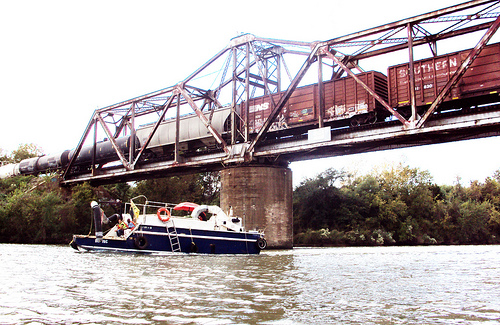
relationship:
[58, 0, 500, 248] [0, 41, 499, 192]
bridge has a train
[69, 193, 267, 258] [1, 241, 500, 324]
boat in water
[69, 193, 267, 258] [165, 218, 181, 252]
boat has a ladder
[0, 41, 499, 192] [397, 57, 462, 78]
train has writing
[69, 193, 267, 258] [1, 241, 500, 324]
boat on water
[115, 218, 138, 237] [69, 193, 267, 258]
people are on boat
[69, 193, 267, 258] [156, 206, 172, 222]
boat has a life saver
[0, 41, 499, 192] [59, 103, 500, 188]
train on tracks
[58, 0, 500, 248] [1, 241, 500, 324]
bridge above water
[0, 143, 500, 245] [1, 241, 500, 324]
trees are near water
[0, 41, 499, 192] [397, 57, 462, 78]
train has large lettering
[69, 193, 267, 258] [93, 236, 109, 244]
boat has writing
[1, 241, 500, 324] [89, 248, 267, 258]
water has shadows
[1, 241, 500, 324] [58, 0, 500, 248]
water under a bridge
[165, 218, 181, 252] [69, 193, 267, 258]
ladder on a boat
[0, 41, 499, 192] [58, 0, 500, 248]
train on a bridge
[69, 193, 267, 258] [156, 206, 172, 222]
boat has a life preserver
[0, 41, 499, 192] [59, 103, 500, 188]
train running on tracks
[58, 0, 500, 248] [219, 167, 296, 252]
bridge has a cement pier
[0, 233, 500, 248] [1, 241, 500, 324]
rocks are alongside water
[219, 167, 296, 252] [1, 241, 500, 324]
concrete pillar in water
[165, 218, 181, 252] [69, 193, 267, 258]
ladder on side of a boat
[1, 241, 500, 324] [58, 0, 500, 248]
water near a bridge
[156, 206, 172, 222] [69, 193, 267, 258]
life raft on a boat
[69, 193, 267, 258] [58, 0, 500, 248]
boat passing under a bridge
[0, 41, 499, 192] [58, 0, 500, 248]
train passing over a bridge